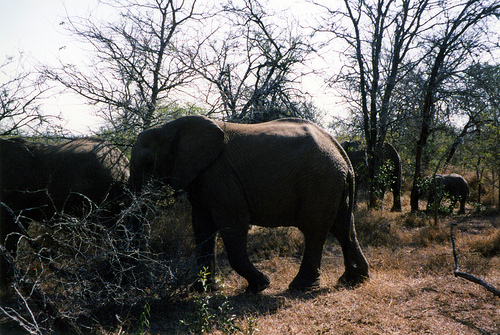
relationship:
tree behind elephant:
[101, 8, 237, 92] [138, 108, 401, 289]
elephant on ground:
[138, 108, 401, 289] [305, 277, 446, 324]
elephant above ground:
[138, 108, 401, 289] [305, 277, 446, 324]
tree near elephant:
[101, 8, 237, 92] [138, 108, 401, 289]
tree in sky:
[101, 8, 237, 92] [20, 5, 98, 59]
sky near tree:
[20, 5, 98, 59] [101, 8, 237, 92]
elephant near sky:
[138, 108, 401, 289] [20, 5, 98, 59]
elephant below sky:
[138, 108, 401, 289] [20, 5, 98, 59]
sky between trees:
[0, 1, 500, 138] [0, 7, 470, 159]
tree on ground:
[101, 8, 237, 92] [28, 157, 464, 330]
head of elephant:
[68, 88, 217, 257] [139, 101, 417, 293]